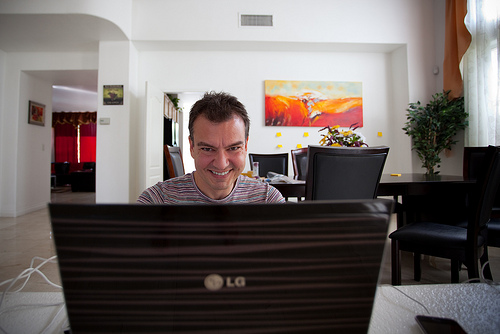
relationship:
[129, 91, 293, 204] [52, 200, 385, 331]
man using laptop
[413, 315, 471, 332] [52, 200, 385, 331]
phone next to laptop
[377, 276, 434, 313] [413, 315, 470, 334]
cable attached to phone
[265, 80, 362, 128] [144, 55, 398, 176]
painting on wall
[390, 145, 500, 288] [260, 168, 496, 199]
black chair in front of table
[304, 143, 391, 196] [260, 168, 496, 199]
chair in front of table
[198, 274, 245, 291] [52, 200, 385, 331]
logo on laptop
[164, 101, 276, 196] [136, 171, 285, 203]
man smiling wearing shirt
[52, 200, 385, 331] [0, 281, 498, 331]
laptop on table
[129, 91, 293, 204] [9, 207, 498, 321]
man sitting behind table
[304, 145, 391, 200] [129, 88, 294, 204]
chair behind man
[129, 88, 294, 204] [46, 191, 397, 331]
man on laptop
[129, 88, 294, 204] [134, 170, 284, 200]
man wearing shirt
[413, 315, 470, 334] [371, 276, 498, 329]
phone on table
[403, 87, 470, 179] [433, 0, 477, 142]
plant next to curtain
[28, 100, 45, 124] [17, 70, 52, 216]
picture on wall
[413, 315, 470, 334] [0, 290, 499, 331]
phone sitting on desk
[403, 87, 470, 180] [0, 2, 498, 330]
plant in corner of room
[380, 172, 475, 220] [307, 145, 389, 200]
table and chair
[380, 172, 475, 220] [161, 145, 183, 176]
table and chair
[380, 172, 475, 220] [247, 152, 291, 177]
table and chair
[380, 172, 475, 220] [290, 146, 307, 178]
table and chair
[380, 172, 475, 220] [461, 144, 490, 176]
table and chair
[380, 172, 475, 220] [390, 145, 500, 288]
table and black chair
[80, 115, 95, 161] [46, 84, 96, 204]
curtain in other room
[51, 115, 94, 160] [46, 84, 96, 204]
curtain in other room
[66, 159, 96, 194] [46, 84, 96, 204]
chair in other room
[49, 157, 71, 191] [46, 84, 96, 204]
chair in other room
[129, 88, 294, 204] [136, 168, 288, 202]
man has shirt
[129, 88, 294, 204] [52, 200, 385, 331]
man sits behind laptop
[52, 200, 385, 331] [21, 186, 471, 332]
laptop on table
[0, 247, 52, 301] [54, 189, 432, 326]
cables behind laptop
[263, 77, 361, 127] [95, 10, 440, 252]
picture on wall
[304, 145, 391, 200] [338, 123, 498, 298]
chair at table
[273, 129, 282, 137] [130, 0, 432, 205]
sticker on wall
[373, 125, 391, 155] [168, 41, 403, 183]
sticker on wall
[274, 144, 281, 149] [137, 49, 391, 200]
sticker on wall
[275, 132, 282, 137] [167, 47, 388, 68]
sticker on wall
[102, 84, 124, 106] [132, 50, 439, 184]
picture on wall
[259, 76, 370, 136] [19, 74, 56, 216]
picture on wall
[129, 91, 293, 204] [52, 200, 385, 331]
man in front of laptop